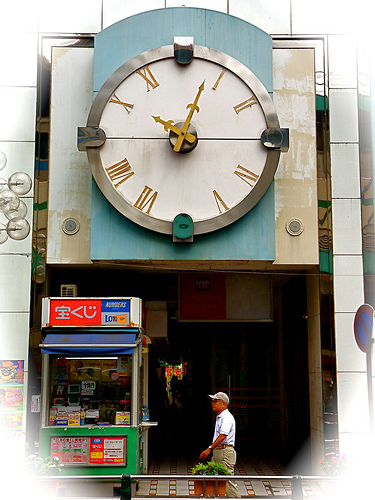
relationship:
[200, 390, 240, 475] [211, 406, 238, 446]
man wearing shirt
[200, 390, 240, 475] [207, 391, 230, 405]
man wearing cap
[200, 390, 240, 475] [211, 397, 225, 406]
man wearing sunglasses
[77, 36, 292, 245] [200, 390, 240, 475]
clock above man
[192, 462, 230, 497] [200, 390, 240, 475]
plants behind man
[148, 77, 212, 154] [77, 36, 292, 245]
hands of clock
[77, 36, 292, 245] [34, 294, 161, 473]
clock above vendor stand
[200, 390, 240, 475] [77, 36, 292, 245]
man below clock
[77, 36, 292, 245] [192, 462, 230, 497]
clock above plants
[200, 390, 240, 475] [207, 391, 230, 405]
man with cap